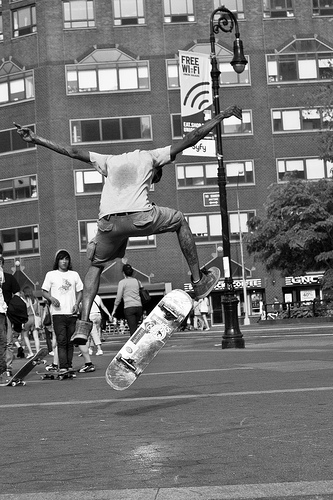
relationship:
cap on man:
[51, 243, 65, 255] [35, 243, 97, 392]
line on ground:
[0, 381, 332, 414] [2, 321, 332, 498]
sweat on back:
[109, 160, 140, 189] [99, 152, 149, 218]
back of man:
[99, 152, 149, 218] [11, 103, 243, 344]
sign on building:
[202, 190, 220, 208] [0, 0, 332, 323]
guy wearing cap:
[41, 248, 84, 371] [53, 246, 72, 263]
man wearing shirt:
[12, 103, 243, 345] [86, 133, 179, 232]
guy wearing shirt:
[41, 248, 84, 371] [39, 268, 85, 316]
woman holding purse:
[113, 262, 142, 324] [137, 284, 155, 307]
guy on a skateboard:
[41, 248, 83, 372] [38, 366, 74, 376]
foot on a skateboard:
[58, 366, 67, 375] [38, 366, 74, 376]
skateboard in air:
[103, 287, 194, 390] [0, 300, 332, 474]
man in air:
[2, 97, 239, 358] [186, 234, 285, 381]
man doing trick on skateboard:
[12, 103, 243, 345] [103, 287, 194, 390]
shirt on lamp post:
[80, 150, 172, 213] [208, 6, 248, 351]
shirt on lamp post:
[39, 268, 89, 316] [208, 6, 248, 351]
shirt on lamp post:
[108, 278, 153, 309] [208, 6, 248, 351]